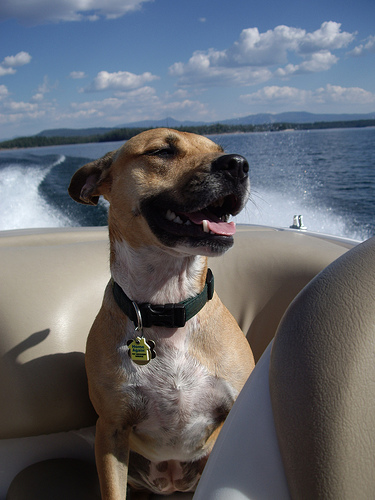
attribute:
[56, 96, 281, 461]
dog — happy, white, brown, black, wearing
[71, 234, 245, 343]
collar — green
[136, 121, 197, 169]
eye — black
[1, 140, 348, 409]
boat — tan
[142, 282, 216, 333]
clasp — black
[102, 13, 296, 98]
sky — blue